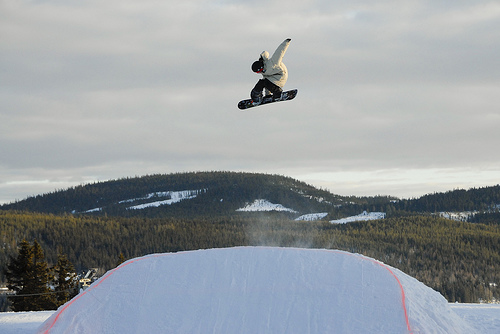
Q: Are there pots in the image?
A: No, there are no pots.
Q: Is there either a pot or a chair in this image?
A: No, there are no pots or chairs.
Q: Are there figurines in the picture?
A: No, there are no figurines.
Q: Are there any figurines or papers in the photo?
A: No, there are no figurines or papers.